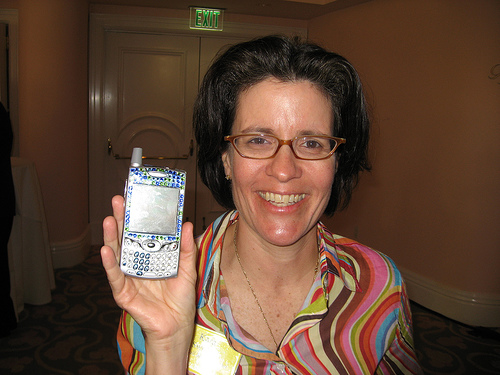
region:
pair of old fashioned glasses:
[211, 122, 355, 174]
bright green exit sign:
[181, 6, 233, 40]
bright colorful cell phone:
[99, 134, 198, 291]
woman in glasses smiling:
[191, 25, 388, 262]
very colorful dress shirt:
[84, 212, 434, 373]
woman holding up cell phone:
[74, 11, 452, 373]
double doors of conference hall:
[81, 5, 325, 278]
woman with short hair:
[183, 25, 395, 280]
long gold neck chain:
[213, 206, 337, 351]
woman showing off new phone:
[18, 2, 459, 374]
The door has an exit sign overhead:
[162, 4, 241, 44]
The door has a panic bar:
[83, 102, 198, 181]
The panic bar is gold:
[106, 132, 196, 176]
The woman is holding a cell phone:
[108, 125, 205, 314]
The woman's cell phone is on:
[98, 143, 198, 311]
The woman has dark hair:
[178, 31, 385, 238]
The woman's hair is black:
[181, 30, 406, 251]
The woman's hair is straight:
[181, 37, 386, 243]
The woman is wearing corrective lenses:
[223, 115, 345, 172]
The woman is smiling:
[237, 176, 343, 238]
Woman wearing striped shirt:
[102, 32, 420, 374]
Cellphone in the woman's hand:
[118, 145, 183, 277]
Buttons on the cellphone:
[120, 238, 178, 276]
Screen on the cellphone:
[129, 183, 178, 233]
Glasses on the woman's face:
[219, 131, 348, 159]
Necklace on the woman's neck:
[232, 220, 279, 347]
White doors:
[87, 8, 303, 248]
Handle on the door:
[112, 151, 191, 162]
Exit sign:
[187, 7, 224, 31]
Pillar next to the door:
[8, 0, 90, 266]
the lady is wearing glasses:
[176, 94, 368, 181]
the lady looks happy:
[191, 23, 396, 239]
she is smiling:
[206, 15, 372, 252]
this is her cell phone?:
[111, 138, 205, 300]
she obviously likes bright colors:
[80, 10, 418, 369]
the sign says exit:
[180, 1, 233, 32]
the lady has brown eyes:
[209, 124, 359, 194]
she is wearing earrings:
[209, 162, 245, 187]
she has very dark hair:
[203, 32, 389, 245]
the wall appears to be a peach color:
[396, 47, 475, 190]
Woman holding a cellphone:
[89, 55, 402, 341]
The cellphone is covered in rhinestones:
[115, 151, 183, 279]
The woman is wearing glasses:
[222, 113, 341, 162]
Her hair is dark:
[188, 54, 375, 214]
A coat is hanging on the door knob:
[2, 140, 68, 321]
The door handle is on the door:
[100, 80, 216, 175]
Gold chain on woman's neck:
[217, 230, 289, 367]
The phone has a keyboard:
[127, 232, 174, 274]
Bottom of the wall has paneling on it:
[412, 259, 497, 310]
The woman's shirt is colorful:
[195, 219, 458, 369]